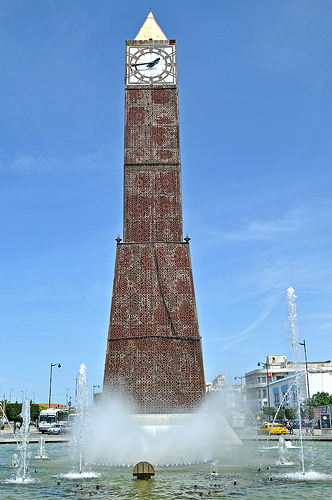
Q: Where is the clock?
A: In the tower.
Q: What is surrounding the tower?
A: Fountains.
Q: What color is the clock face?
A: White.